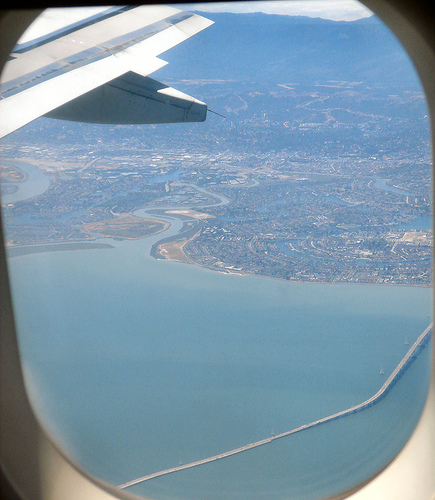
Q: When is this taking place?
A: Daytime.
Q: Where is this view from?
A: Plane.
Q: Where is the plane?
A: Sky.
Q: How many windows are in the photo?
A: One.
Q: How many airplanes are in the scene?
A: One.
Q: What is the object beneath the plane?
A: Body of water.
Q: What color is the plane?
A: White and blue.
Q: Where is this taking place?
A: From an airplane in the sky.